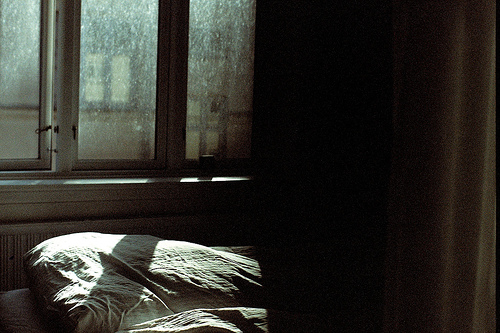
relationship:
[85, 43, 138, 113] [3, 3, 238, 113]
window on building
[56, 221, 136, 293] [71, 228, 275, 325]
light falling on pillow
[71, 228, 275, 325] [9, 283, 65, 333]
pillow lying on bed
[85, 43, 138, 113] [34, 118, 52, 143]
window has latch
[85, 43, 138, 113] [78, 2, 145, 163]
window has glass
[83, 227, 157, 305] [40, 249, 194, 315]
shadows falling on cloth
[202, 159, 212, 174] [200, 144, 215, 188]
water inside glass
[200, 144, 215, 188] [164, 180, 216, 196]
glass has shadow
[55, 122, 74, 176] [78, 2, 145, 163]
wood connects glass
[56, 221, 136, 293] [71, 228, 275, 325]
light reflects on pillow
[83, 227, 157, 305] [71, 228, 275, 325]
shadows across pillow